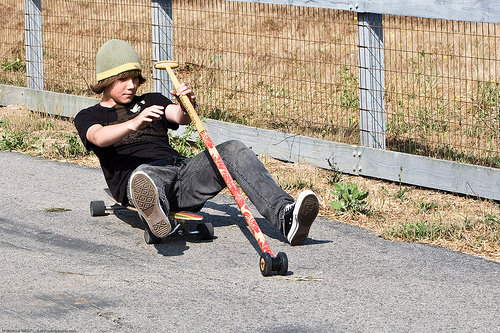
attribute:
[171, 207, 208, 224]
tip — red, yellow, green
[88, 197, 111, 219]
wheel — black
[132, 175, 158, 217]
tread — tan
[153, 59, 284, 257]
pole — long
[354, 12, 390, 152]
post — wooden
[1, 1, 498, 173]
fencing — wired, wood, metal, steel, mesh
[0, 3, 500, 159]
grass — dry, golden, brown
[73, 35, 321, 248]
guy — skateboarding, sitting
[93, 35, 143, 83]
cap — olive, yellow, grey, sage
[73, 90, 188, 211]
t-shirt — black, short sleeved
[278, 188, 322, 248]
sneaker — high top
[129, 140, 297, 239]
jeans — scrubby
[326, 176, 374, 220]
weed — green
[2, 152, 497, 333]
pavement — gray